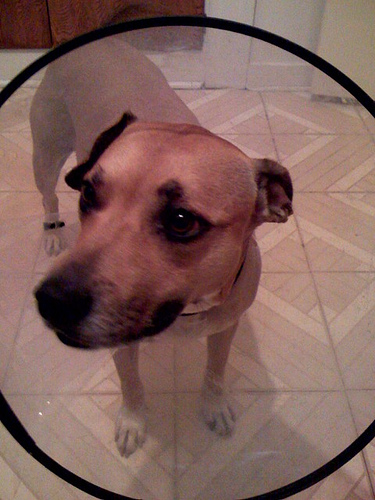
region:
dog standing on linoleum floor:
[11, 35, 294, 460]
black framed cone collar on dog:
[5, 12, 373, 499]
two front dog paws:
[108, 394, 248, 462]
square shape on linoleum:
[209, 90, 340, 172]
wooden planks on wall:
[1, 1, 209, 56]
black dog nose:
[27, 277, 101, 328]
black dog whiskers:
[90, 280, 159, 366]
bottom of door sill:
[1, 69, 253, 98]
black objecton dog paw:
[40, 211, 70, 235]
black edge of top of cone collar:
[179, 253, 256, 324]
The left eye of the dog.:
[75, 178, 101, 201]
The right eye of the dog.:
[138, 195, 209, 243]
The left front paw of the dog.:
[107, 392, 144, 448]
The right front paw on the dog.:
[195, 390, 233, 428]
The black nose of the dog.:
[32, 270, 83, 320]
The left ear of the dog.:
[60, 111, 123, 171]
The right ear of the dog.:
[255, 151, 293, 218]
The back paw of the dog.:
[35, 210, 65, 248]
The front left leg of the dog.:
[109, 341, 140, 397]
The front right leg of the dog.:
[204, 330, 242, 386]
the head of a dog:
[31, 106, 298, 358]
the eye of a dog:
[151, 198, 213, 247]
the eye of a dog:
[71, 174, 100, 208]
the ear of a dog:
[247, 151, 295, 231]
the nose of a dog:
[27, 271, 92, 334]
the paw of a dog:
[107, 403, 148, 457]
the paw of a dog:
[197, 390, 241, 438]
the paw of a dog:
[35, 221, 71, 256]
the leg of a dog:
[195, 337, 245, 435]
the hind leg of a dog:
[26, 118, 75, 259]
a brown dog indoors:
[12, 10, 307, 472]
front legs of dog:
[90, 337, 250, 473]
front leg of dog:
[30, 141, 72, 262]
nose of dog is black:
[30, 264, 98, 336]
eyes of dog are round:
[67, 180, 213, 248]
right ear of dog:
[246, 147, 309, 233]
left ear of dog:
[49, 102, 145, 197]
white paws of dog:
[100, 396, 244, 468]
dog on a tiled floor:
[0, 41, 363, 473]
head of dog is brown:
[18, 113, 298, 355]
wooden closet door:
[0, 0, 204, 48]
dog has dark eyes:
[156, 205, 206, 241]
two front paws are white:
[115, 391, 234, 454]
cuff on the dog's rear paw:
[43, 219, 66, 229]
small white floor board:
[0, 76, 204, 87]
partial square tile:
[309, 270, 372, 393]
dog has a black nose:
[32, 279, 94, 327]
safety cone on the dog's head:
[0, 18, 371, 499]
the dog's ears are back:
[251, 157, 293, 222]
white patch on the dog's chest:
[158, 292, 231, 334]